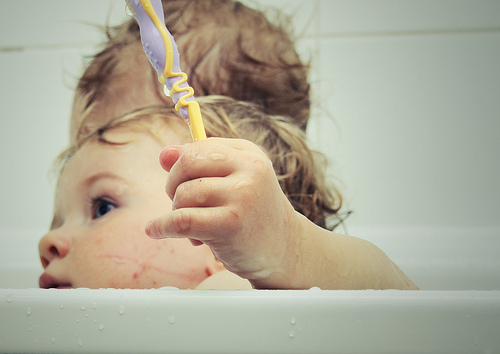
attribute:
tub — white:
[0, 283, 499, 354]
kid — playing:
[34, 85, 422, 291]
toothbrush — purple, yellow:
[124, 1, 211, 145]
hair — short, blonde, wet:
[46, 91, 356, 233]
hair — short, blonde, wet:
[66, 16, 319, 140]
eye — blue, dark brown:
[81, 186, 128, 225]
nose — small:
[31, 225, 78, 265]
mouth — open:
[32, 269, 79, 290]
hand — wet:
[137, 129, 298, 279]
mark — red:
[124, 265, 146, 285]